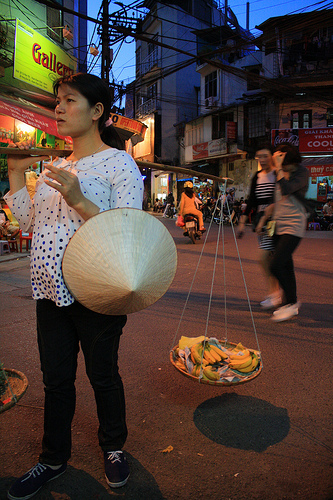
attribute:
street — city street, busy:
[1, 218, 332, 499]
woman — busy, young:
[6, 73, 143, 498]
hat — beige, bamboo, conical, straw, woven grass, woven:
[60, 207, 179, 316]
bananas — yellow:
[189, 338, 260, 382]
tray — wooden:
[168, 340, 264, 385]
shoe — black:
[102, 449, 131, 489]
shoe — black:
[5, 464, 69, 500]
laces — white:
[20, 459, 47, 482]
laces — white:
[106, 451, 124, 465]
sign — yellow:
[13, 19, 79, 96]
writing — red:
[32, 43, 74, 80]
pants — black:
[35, 299, 127, 466]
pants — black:
[267, 235, 303, 304]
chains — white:
[170, 179, 264, 383]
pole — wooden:
[2, 148, 235, 186]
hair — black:
[53, 73, 125, 151]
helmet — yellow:
[183, 181, 193, 189]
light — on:
[35, 27, 75, 43]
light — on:
[64, 44, 98, 57]